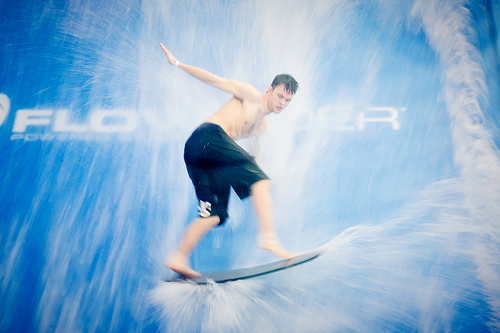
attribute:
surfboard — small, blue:
[162, 252, 317, 290]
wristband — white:
[175, 62, 180, 66]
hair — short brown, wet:
[246, 66, 305, 125]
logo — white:
[196, 197, 218, 219]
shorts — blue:
[178, 124, 283, 210]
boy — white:
[227, 58, 307, 143]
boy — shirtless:
[167, 74, 303, 278]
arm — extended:
[159, 46, 244, 98]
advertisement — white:
[4, 90, 447, 149]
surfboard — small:
[154, 245, 334, 285]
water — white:
[2, 2, 497, 330]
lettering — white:
[9, 103, 411, 138]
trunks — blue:
[164, 115, 292, 243]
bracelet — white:
[172, 60, 179, 65]